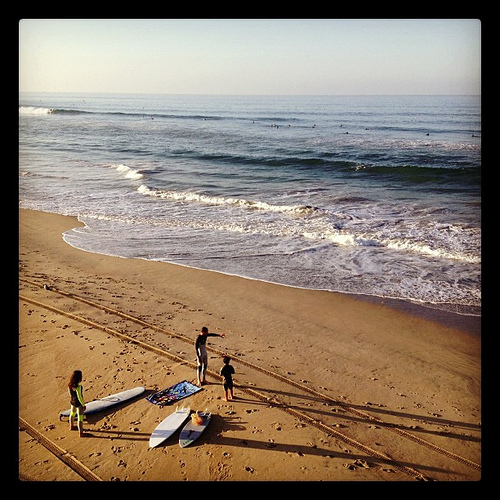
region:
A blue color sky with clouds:
[219, 28, 401, 73]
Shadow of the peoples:
[268, 378, 390, 459]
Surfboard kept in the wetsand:
[109, 393, 217, 445]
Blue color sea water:
[253, 90, 388, 166]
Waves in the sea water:
[21, 100, 122, 117]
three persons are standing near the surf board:
[56, 327, 257, 447]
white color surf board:
[155, 408, 210, 450]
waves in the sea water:
[189, 92, 466, 187]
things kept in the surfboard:
[191, 405, 203, 429]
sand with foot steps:
[46, 290, 154, 370]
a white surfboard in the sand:
[58, 382, 147, 419]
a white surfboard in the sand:
[145, 400, 192, 450]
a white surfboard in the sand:
[177, 409, 216, 449]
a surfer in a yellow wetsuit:
[65, 365, 90, 437]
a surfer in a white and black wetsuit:
[195, 325, 225, 384]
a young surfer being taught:
[220, 358, 238, 402]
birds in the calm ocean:
[250, 118, 476, 139]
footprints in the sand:
[22, 258, 471, 475]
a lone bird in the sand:
[40, 278, 52, 293]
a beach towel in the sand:
[146, 378, 203, 408]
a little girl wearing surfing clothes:
[65, 371, 95, 433]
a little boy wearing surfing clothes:
[214, 353, 245, 405]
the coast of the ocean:
[194, 145, 306, 300]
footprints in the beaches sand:
[268, 432, 333, 470]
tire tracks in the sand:
[51, 269, 143, 350]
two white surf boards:
[132, 403, 209, 447]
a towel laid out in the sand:
[131, 356, 203, 404]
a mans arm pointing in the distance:
[207, 325, 232, 346]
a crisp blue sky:
[194, 46, 245, 77]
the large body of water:
[20, 90, 480, 315]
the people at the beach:
[67, 327, 234, 438]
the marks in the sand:
[19, 208, 479, 480]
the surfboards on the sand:
[59, 385, 212, 447]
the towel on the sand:
[145, 378, 202, 408]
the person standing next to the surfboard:
[65, 368, 87, 437]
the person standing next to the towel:
[195, 326, 225, 385]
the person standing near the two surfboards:
[218, 355, 233, 400]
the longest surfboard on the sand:
[58, 385, 145, 420]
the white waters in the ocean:
[20, 103, 482, 316]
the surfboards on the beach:
[144, 403, 218, 463]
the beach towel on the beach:
[148, 378, 203, 410]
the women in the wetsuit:
[59, 363, 95, 433]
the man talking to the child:
[189, 317, 247, 403]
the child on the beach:
[220, 354, 237, 399]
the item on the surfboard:
[186, 410, 208, 427]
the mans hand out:
[207, 328, 226, 341]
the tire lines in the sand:
[40, 277, 152, 359]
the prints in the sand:
[110, 447, 346, 472]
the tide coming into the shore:
[16, 144, 479, 264]